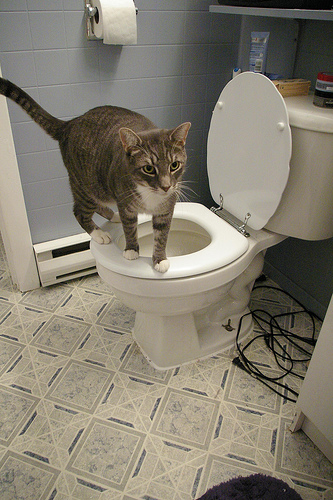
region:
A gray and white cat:
[2, 80, 189, 274]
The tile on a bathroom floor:
[4, 373, 213, 483]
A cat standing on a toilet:
[1, 72, 265, 316]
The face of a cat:
[117, 120, 192, 204]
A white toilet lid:
[204, 70, 295, 235]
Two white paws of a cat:
[119, 245, 175, 273]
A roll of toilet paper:
[83, 1, 141, 48]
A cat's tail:
[1, 77, 62, 139]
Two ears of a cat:
[117, 120, 191, 152]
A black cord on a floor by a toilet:
[232, 272, 322, 399]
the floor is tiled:
[19, 336, 202, 487]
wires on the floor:
[233, 298, 313, 413]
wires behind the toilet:
[155, 291, 304, 416]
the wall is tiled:
[2, 5, 90, 119]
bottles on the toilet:
[242, 27, 331, 111]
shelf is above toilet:
[208, 1, 332, 140]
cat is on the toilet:
[28, 82, 260, 300]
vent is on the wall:
[31, 231, 110, 288]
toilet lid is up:
[199, 70, 287, 249]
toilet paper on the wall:
[78, 3, 158, 95]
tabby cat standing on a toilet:
[4, 68, 265, 374]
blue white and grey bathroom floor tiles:
[29, 350, 126, 431]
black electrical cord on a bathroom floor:
[241, 281, 314, 399]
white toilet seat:
[95, 203, 224, 283]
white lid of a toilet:
[203, 63, 302, 237]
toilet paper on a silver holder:
[78, 0, 154, 63]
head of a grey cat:
[117, 127, 197, 198]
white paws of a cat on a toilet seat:
[79, 196, 176, 285]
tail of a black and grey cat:
[0, 79, 65, 152]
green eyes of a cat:
[135, 159, 184, 178]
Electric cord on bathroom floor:
[232, 282, 320, 407]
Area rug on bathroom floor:
[185, 472, 306, 497]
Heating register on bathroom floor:
[31, 232, 97, 290]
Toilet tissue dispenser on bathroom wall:
[80, 2, 146, 48]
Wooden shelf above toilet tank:
[202, 3, 330, 29]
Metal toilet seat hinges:
[209, 194, 252, 240]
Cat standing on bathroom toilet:
[2, 73, 195, 275]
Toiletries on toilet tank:
[232, 29, 330, 110]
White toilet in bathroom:
[88, 71, 332, 371]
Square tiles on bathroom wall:
[36, 44, 211, 104]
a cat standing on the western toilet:
[74, 76, 243, 376]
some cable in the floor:
[250, 275, 317, 406]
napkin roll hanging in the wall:
[75, 0, 149, 45]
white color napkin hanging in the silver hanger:
[76, 0, 145, 44]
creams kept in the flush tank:
[310, 65, 329, 110]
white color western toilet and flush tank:
[71, 74, 327, 362]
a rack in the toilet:
[207, 1, 330, 28]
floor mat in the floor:
[218, 465, 316, 493]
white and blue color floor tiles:
[19, 351, 149, 485]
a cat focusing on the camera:
[6, 75, 186, 270]